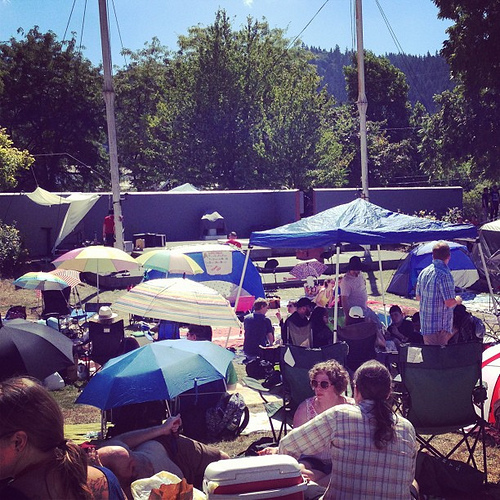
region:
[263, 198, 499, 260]
a blue canopy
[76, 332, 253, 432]
person holding a blue umbrella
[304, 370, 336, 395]
woman wearing sunglasses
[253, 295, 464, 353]
people sitting under a blue canopy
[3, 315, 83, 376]
a black umbrella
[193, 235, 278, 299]
a blue tent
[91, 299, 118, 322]
a straw hat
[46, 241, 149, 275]
a multicolored umbrella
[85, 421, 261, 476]
man laying down on the grass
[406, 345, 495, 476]
a black folding chair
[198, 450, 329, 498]
the cooler is red and white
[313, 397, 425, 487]
the shirt has stripes on it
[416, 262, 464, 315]
the shirt is blue and white plaid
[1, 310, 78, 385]
the umbrella is black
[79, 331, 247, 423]
the umbrella is blue in color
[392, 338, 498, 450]
the chair is dark green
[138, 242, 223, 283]
the umbrella is yellow green and faded orange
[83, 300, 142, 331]
the hat is white with a brown stripe on it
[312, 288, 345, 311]
the shirt is yellow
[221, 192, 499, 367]
the pole tent is blue with white ploes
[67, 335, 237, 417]
Blue umbrella in the sun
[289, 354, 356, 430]
Curly-haired woman wearing sunglasses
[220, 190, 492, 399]
Group sitting under blue tent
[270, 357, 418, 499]
Man with ponytail wearing plaid shirt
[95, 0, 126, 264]
Tall white metal tower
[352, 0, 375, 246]
Tall white metal tower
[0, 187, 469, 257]
Gray painted brick wall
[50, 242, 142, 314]
Rainbow beach umbrella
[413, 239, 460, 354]
Man in blue plaid shirt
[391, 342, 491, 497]
Green canvas camping chair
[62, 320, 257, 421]
The umbrella is blue.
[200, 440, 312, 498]
The cooler is red and white.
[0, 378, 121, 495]
The woman has her hair in a pony tail.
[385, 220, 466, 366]
The man is wearing a blue and white shirt.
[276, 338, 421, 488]
Two people sitting next to each other.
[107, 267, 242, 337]
An umbrella with stripes on it.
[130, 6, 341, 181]
The tree is green.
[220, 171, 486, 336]
The canopy is blue.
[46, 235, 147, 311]
The umbrella is multicolored.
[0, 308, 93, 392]
The umbrella is black.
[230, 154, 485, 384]
small dark blue tent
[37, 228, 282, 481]
people holding umbrellas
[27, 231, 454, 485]
large gathering of people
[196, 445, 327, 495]
red and white cooler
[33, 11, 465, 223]
group of trees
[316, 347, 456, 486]
man wearing his hair in a pony tail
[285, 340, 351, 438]
woman with short curly hair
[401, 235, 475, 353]
man wearing a checkered shirt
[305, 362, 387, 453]
large dark sunglasses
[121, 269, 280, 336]
multi-colored striped umbrella